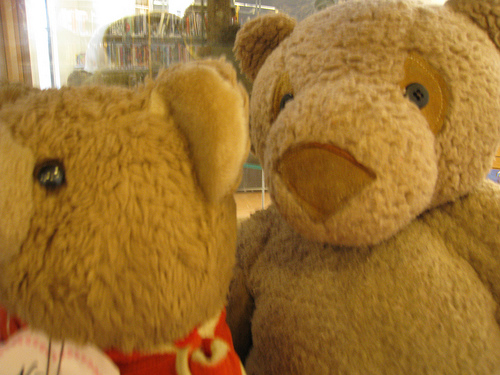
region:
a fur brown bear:
[222, 0, 498, 373]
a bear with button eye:
[402, 81, 429, 111]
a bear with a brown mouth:
[272, 135, 377, 221]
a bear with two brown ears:
[230, 0, 498, 87]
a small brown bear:
[0, 61, 245, 371]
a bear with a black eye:
[30, 155, 65, 190]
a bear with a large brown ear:
[147, 55, 247, 200]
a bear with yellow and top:
[0, 300, 245, 370]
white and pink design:
[0, 322, 121, 372]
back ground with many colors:
[0, 0, 311, 217]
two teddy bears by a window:
[11, 3, 496, 279]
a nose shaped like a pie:
[260, 113, 379, 240]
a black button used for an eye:
[390, 58, 459, 125]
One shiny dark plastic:
[33, 145, 85, 220]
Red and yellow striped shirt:
[75, 305, 330, 373]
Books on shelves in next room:
[39, 5, 253, 80]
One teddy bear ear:
[124, 39, 262, 211]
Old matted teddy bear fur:
[279, 23, 409, 171]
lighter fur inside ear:
[138, 23, 262, 206]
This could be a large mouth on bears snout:
[253, 130, 408, 224]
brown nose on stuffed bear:
[273, 142, 377, 220]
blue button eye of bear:
[406, 82, 426, 110]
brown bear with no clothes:
[226, 0, 496, 372]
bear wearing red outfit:
[2, 304, 249, 374]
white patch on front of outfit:
[1, 326, 121, 373]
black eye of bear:
[41, 160, 64, 188]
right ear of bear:
[153, 55, 253, 199]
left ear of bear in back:
[233, 12, 295, 79]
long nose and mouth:
[262, 81, 438, 244]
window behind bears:
[14, 0, 499, 205]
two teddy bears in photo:
[4, 24, 488, 358]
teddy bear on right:
[250, 22, 490, 347]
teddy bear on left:
[7, 71, 229, 372]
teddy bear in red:
[7, 62, 244, 364]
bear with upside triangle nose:
[220, 20, 497, 344]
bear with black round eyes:
[42, 155, 84, 205]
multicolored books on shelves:
[96, 25, 151, 66]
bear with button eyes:
[398, 62, 452, 130]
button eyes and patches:
[395, 50, 459, 160]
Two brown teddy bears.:
[2, 2, 498, 373]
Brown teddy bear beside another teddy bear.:
[232, 1, 499, 373]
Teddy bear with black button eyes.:
[234, 17, 499, 373]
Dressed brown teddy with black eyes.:
[1, 59, 251, 372]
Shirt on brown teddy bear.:
[0, 306, 245, 371]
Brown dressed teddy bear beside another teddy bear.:
[0, 60, 247, 372]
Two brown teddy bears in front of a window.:
[0, 0, 495, 370]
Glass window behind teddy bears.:
[2, 0, 497, 230]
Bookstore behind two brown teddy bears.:
[10, 0, 496, 365]